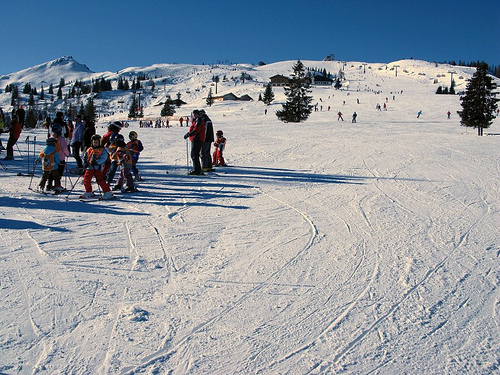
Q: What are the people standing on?
A: Snow.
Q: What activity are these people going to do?
A: Skiing.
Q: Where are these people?
A: On a ski mountain.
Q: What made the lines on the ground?
A: Skis.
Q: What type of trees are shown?
A: Evergreen.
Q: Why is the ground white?
A: Snow.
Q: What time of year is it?
A: Winter.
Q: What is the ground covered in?
A: Snow.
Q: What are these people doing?
A: Standing in snow.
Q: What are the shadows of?
A: The crowd.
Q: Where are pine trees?
A: Behind people.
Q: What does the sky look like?
A: Clear blue.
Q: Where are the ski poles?
A: People are holding them.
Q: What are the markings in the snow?
A: Tracks.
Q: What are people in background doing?
A: Skiing.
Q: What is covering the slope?
A: Snow.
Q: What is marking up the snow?
A: Ski tracks.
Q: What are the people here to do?
A: Ski.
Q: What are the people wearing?
A: Skis.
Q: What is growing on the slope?
A: Trees.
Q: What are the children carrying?
A: Ski poles.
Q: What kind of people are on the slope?
A: Skiers.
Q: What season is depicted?
A: Winter.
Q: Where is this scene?
A: Ski slope.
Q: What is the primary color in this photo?
A: White.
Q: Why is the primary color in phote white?
A: Its snow.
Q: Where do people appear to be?
A: Ski slope.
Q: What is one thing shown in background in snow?
A: Trees.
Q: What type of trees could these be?
A: Pine.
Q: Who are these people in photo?
A: Skiers.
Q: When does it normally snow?
A: Winter.